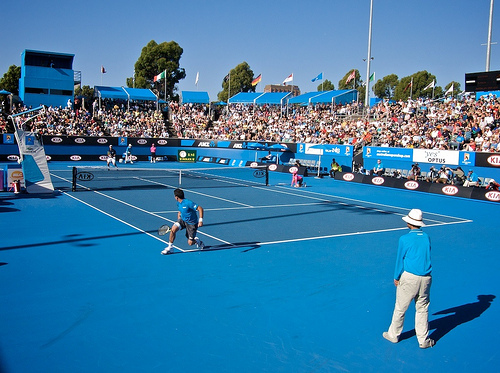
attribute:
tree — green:
[388, 62, 437, 114]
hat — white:
[402, 211, 427, 225]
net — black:
[68, 161, 270, 191]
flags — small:
[97, 67, 463, 95]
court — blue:
[3, 159, 498, 371]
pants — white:
[384, 270, 434, 348]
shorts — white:
[105, 154, 116, 164]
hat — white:
[400, 208, 430, 229]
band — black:
[405, 213, 423, 223]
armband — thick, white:
[195, 216, 203, 226]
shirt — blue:
[394, 229, 432, 283]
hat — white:
[402, 209, 426, 236]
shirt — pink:
[149, 143, 157, 153]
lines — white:
[35, 165, 471, 252]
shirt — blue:
[175, 199, 201, 229]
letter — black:
[425, 153, 434, 164]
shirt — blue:
[175, 203, 199, 219]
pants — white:
[388, 274, 433, 340]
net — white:
[67, 168, 270, 188]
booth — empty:
[4, 100, 57, 193]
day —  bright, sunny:
[13, 58, 498, 373]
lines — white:
[51, 131, 455, 234]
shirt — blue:
[398, 234, 426, 274]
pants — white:
[400, 291, 430, 306]